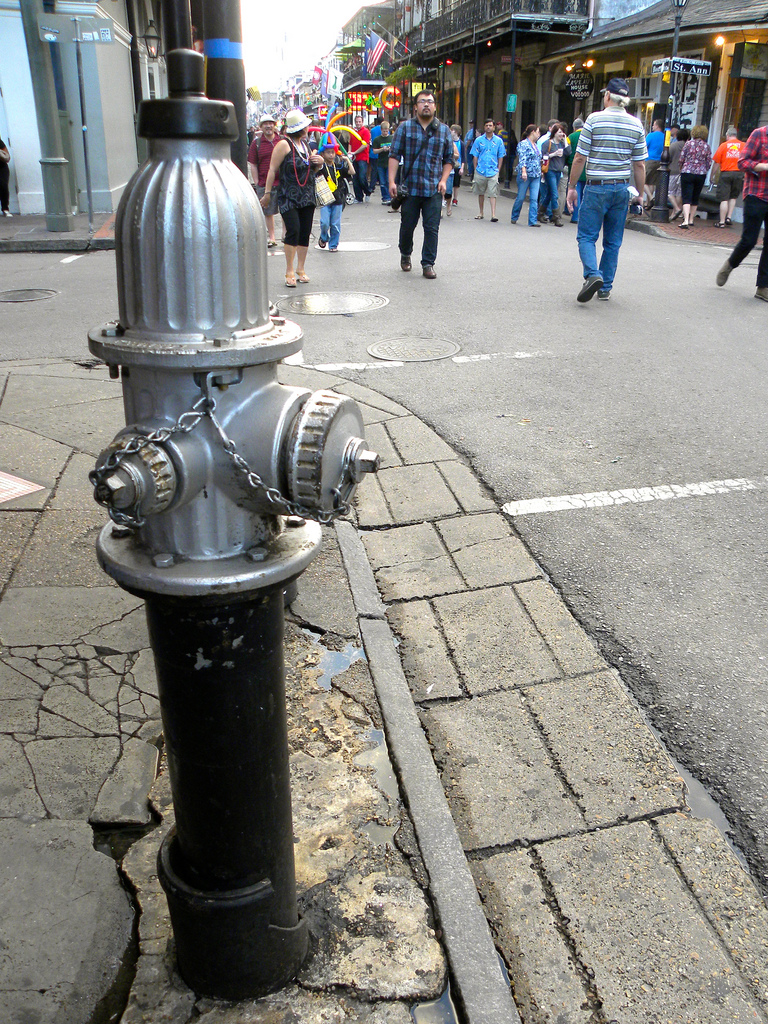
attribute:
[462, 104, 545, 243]
person — white, walking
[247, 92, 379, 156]
hat — white 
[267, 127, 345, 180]
necklace — red 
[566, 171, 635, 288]
blue jeans — blue 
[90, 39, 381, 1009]
hydrant — black and silver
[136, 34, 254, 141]
top — black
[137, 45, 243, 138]
tip — black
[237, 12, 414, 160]
sky — overcast